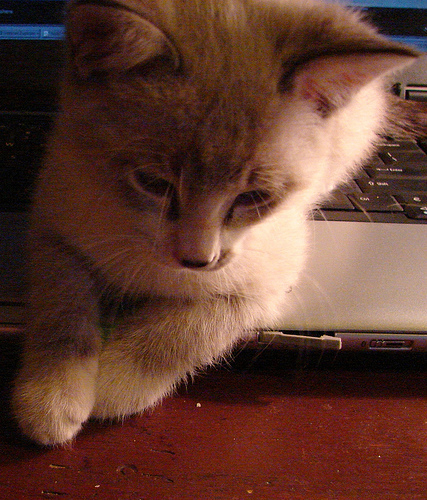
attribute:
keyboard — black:
[6, 111, 424, 220]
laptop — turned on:
[0, 4, 424, 352]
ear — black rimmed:
[290, 40, 420, 127]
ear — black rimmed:
[62, 1, 187, 92]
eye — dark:
[231, 184, 269, 213]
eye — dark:
[134, 169, 176, 205]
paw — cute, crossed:
[6, 349, 98, 448]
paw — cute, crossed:
[88, 319, 175, 420]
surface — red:
[8, 222, 423, 351]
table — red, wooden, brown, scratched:
[0, 356, 424, 498]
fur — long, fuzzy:
[6, 0, 389, 451]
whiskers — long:
[32, 228, 159, 344]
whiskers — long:
[195, 248, 333, 344]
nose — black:
[175, 257, 212, 274]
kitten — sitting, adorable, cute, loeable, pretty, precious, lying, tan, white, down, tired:
[11, 0, 421, 437]